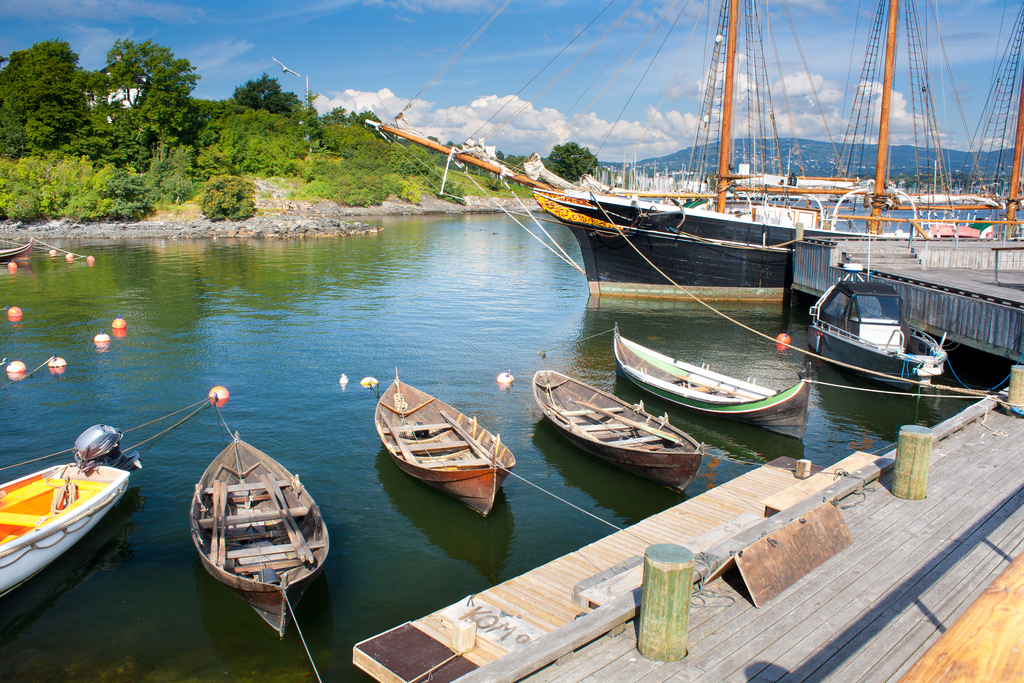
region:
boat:
[362, 367, 517, 510]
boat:
[181, 408, 321, 609]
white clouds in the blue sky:
[207, 19, 303, 89]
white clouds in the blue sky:
[389, 83, 462, 132]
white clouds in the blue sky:
[497, 13, 573, 56]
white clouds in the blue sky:
[576, 75, 663, 130]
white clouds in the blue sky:
[827, 48, 929, 118]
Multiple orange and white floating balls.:
[3, 218, 381, 411]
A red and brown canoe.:
[378, 376, 522, 516]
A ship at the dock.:
[357, 13, 1021, 305]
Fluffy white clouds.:
[331, 67, 914, 145]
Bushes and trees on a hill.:
[10, 30, 548, 227]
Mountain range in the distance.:
[603, 122, 1021, 176]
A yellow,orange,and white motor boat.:
[0, 428, 133, 588]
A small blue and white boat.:
[797, 260, 965, 397]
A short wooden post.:
[635, 539, 700, 650]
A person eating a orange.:
[508, 311, 613, 476]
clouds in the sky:
[316, 70, 728, 165]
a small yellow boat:
[2, 454, 133, 607]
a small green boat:
[615, 329, 812, 418]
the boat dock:
[539, 476, 1021, 673]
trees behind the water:
[15, 47, 497, 218]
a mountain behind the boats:
[632, 117, 1005, 195]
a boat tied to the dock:
[375, 364, 664, 554]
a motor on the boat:
[69, 418, 130, 463]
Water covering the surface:
[1, 209, 1000, 675]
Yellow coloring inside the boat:
[0, 416, 131, 609]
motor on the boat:
[55, 416, 154, 484]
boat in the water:
[361, 363, 529, 523]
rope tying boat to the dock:
[798, 360, 986, 406]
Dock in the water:
[320, 367, 1022, 677]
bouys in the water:
[4, 221, 148, 396]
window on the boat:
[833, 287, 901, 323]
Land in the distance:
[593, 124, 1015, 175]